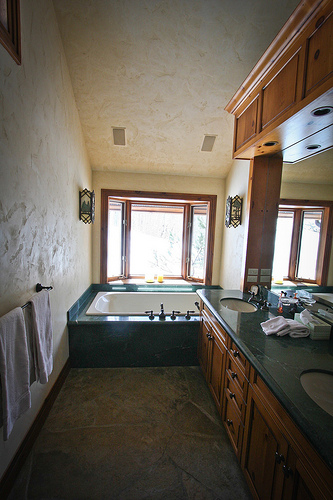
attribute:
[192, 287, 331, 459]
counter — green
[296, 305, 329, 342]
towel — folded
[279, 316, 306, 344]
towel — folded, white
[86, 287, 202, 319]
bath tub — large, white, green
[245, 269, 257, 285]
electrical outlet — white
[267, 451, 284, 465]
knobs — wood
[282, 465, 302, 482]
knobs — wood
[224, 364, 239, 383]
knobs — wood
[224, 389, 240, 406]
knobs — wood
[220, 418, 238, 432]
knobs — wood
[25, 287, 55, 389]
towel — white, folded, hanging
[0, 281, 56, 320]
rod — black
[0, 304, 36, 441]
towel — white, folded, hanging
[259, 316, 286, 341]
towel — white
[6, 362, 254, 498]
floor — marble, faux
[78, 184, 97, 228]
light — pretty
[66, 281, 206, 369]
marble — aqua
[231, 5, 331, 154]
cabinetry — dark brown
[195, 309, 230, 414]
cabinetry — dark brown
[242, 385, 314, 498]
cabinetry — dark brown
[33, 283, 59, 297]
fixture — black